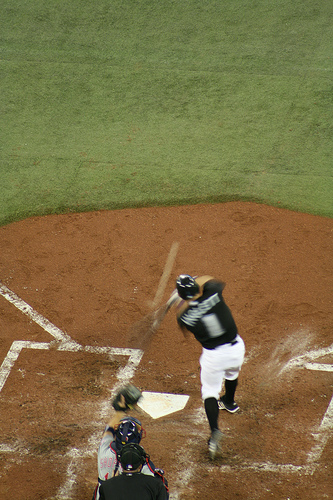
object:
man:
[174, 271, 246, 461]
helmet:
[175, 273, 200, 302]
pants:
[199, 339, 245, 400]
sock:
[204, 393, 219, 438]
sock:
[223, 377, 239, 407]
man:
[90, 385, 158, 498]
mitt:
[110, 382, 141, 410]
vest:
[98, 440, 168, 500]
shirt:
[177, 277, 238, 349]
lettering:
[182, 291, 224, 329]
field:
[2, 2, 332, 499]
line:
[1, 281, 70, 364]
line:
[289, 332, 332, 483]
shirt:
[93, 433, 154, 500]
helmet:
[116, 419, 143, 445]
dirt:
[2, 207, 329, 500]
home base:
[133, 389, 192, 422]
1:
[202, 314, 225, 342]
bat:
[132, 294, 179, 345]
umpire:
[99, 446, 169, 499]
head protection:
[117, 442, 149, 474]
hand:
[172, 287, 183, 301]